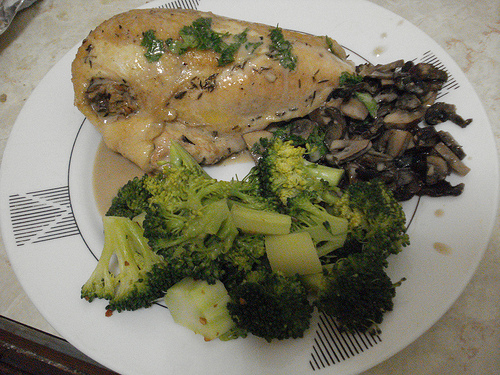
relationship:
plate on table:
[2, 0, 498, 375] [2, 0, 499, 375]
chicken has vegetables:
[68, 8, 358, 172] [139, 23, 313, 74]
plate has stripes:
[2, 0, 498, 375] [4, 184, 81, 249]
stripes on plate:
[4, 184, 81, 249] [2, 0, 498, 375]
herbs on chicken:
[139, 23, 313, 74] [68, 8, 358, 172]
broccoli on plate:
[78, 137, 411, 344] [2, 0, 498, 375]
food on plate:
[71, 9, 472, 343] [2, 0, 498, 375]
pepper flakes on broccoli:
[96, 247, 221, 344] [78, 137, 411, 344]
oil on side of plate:
[372, 29, 396, 60] [2, 0, 498, 375]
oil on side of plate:
[425, 202, 458, 257] [2, 0, 498, 375]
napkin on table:
[0, 0, 50, 46] [2, 0, 499, 375]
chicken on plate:
[68, 8, 358, 172] [2, 0, 498, 375]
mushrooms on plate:
[277, 52, 477, 208] [2, 0, 498, 375]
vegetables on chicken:
[139, 23, 313, 74] [68, 8, 358, 172]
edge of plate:
[0, 52, 72, 323] [2, 0, 498, 375]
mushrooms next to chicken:
[277, 52, 477, 208] [68, 8, 358, 172]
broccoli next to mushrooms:
[78, 137, 411, 344] [277, 52, 477, 208]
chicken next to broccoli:
[68, 8, 358, 172] [78, 137, 411, 344]